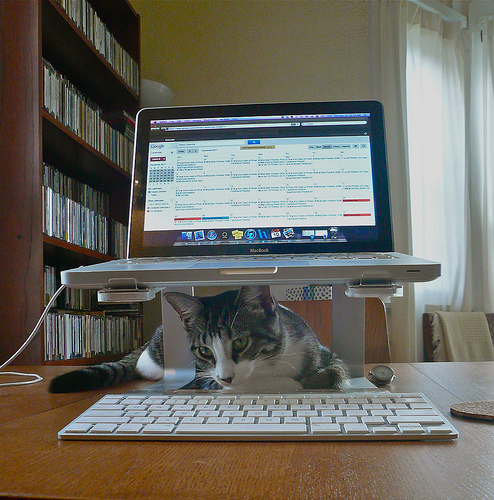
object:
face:
[369, 364, 397, 384]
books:
[47, 315, 142, 360]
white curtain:
[404, 20, 493, 314]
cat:
[46, 281, 346, 394]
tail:
[44, 339, 155, 394]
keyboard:
[56, 389, 465, 444]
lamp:
[137, 71, 175, 110]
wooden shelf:
[0, 1, 143, 368]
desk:
[0, 358, 493, 498]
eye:
[233, 334, 249, 352]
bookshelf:
[0, 0, 147, 371]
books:
[45, 160, 131, 261]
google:
[150, 143, 164, 149]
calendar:
[141, 143, 379, 230]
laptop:
[57, 98, 440, 287]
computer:
[60, 99, 443, 288]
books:
[38, 60, 137, 175]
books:
[60, 23, 142, 93]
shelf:
[40, 78, 131, 176]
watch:
[370, 364, 396, 385]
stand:
[96, 268, 407, 391]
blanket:
[424, 305, 494, 363]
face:
[162, 287, 284, 387]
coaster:
[449, 398, 494, 421]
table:
[0, 358, 494, 499]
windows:
[379, 5, 492, 360]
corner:
[139, 9, 170, 106]